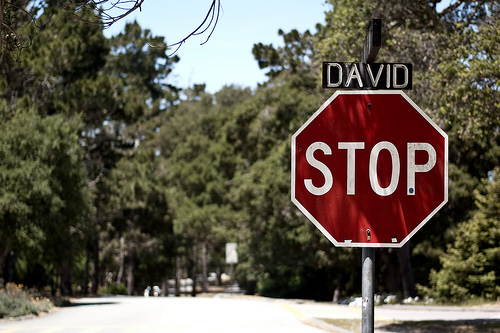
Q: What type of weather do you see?
A: It is clear.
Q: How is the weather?
A: It is clear.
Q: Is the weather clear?
A: Yes, it is clear.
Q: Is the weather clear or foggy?
A: It is clear.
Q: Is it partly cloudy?
A: No, it is clear.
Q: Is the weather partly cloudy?
A: No, it is clear.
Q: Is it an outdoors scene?
A: Yes, it is outdoors.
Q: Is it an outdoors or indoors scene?
A: It is outdoors.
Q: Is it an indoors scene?
A: No, it is outdoors.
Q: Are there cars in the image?
A: No, there are no cars.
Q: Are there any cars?
A: No, there are no cars.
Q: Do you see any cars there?
A: No, there are no cars.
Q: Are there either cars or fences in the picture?
A: No, there are no cars or fences.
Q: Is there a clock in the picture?
A: No, there are no clocks.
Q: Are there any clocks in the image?
A: No, there are no clocks.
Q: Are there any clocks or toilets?
A: No, there are no clocks or toilets.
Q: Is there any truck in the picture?
A: No, there are no trucks.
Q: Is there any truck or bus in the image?
A: No, there are no trucks or buses.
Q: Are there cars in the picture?
A: No, there are no cars.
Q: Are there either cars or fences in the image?
A: No, there are no cars or fences.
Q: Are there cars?
A: No, there are no cars.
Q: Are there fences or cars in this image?
A: No, there are no cars or fences.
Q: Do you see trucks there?
A: No, there are no trucks.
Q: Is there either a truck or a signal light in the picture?
A: No, there are no trucks or traffic lights.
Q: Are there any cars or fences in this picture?
A: No, there are no cars or fences.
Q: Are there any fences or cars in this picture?
A: No, there are no cars or fences.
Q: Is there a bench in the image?
A: No, there are no benches.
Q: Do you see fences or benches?
A: No, there are no benches or fences.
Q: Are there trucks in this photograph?
A: No, there are no trucks.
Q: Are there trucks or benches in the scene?
A: No, there are no trucks or benches.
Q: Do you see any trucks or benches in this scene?
A: No, there are no trucks or benches.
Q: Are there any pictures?
A: No, there are no pictures.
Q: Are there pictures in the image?
A: No, there are no pictures.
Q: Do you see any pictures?
A: No, there are no pictures.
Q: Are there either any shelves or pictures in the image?
A: No, there are no pictures or shelves.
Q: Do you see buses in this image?
A: No, there are no buses.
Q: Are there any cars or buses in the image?
A: No, there are no buses or cars.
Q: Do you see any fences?
A: No, there are no fences.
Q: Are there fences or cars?
A: No, there are no fences or cars.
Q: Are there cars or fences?
A: No, there are no fences or cars.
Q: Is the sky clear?
A: Yes, the sky is clear.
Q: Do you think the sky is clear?
A: Yes, the sky is clear.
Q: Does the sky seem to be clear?
A: Yes, the sky is clear.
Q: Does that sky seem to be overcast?
A: No, the sky is clear.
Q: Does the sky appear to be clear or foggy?
A: The sky is clear.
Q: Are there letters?
A: Yes, there are letters.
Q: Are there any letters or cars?
A: Yes, there are letters.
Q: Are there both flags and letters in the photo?
A: No, there are letters but no flags.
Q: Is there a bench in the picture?
A: No, there are no benches.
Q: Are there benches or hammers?
A: No, there are no benches or hammers.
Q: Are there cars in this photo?
A: No, there are no cars.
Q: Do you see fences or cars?
A: No, there are no cars or fences.